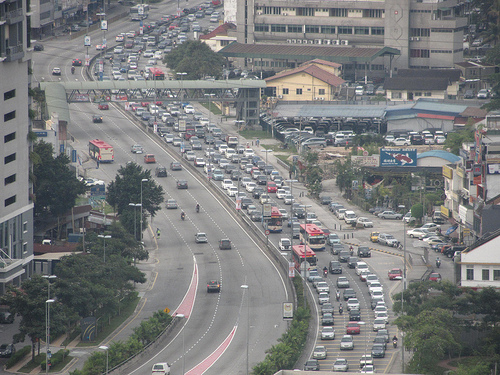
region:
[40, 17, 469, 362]
traffic jam in a city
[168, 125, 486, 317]
very congested area with lots of cars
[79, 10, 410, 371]
traffic jam could be for miles up the road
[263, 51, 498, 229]
buildings in the background look very busy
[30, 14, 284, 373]
the opposite side of the road is clear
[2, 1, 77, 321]
building in the background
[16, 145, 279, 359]
trees next to the road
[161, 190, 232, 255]
two motorcyclists are riding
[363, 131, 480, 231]
the sign on this restaurant cannot be read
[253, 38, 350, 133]
this building is tan and brown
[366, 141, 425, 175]
Sign with a large fish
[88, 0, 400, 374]
A large traffic jam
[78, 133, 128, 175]
A red and white bus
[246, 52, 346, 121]
A tan building with a brown roof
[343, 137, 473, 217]
A restaurant next to the busy road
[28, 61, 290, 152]
A walk way going over the busy street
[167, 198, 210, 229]
Two men riding motorcycles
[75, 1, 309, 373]
A concrete divider to seperate the two roads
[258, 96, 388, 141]
A green awning going over the parked cars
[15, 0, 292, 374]
A road without a lot of traffic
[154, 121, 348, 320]
Cars on a road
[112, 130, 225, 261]
Cars driving on a road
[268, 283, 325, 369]
Bushes on a road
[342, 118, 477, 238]
Building by a road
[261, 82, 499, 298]
Buildings in a city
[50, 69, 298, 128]
Bridge over a road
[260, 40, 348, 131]
House by a road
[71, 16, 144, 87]
Signs by a road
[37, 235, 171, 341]
Green trees by a road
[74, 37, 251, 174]
Cars driving down a road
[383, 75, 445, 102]
White single story house with a black roof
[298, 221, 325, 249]
Large red and white bus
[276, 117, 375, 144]
Parking lot full of parked cars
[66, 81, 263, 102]
Long green walking bridge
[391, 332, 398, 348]
Person riding a motorcycle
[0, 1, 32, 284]
Extremely tall grey building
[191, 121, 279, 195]
Traffic jam on a highway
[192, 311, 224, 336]
Dotted line on a highway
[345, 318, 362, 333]
Front view of a red car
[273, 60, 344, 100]
Yellow house with a brown roof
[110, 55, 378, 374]
cars stuck in traffic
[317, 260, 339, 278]
motorcycle driving between two cars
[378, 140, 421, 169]
red, white, and blue sign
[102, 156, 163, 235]
tree along the side of the road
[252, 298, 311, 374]
shrubbery dividing the two sides of traffic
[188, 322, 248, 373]
red paint on the ground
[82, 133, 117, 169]
red and white bus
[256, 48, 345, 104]
yellow building with a brown roof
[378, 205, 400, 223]
car parked in a parking lot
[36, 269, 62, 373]
street lamp